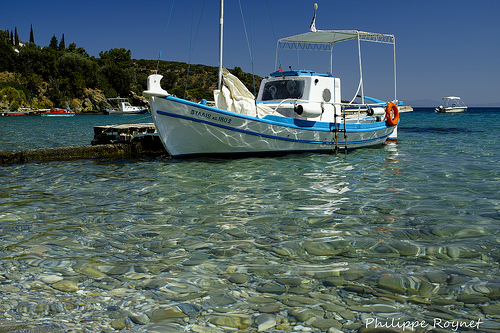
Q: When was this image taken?
A: During the day.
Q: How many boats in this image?
A: Four.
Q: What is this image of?
A: A boat.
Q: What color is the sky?
A: Blue.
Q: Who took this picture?
A: Philippe Roynet.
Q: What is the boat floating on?
A: Water.